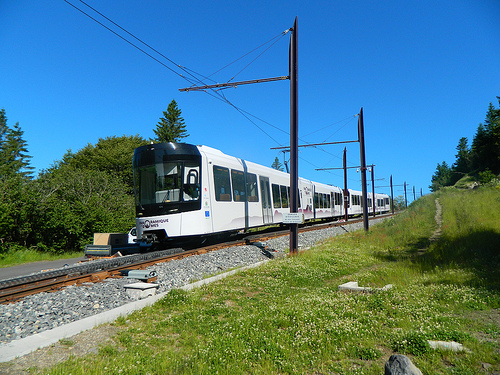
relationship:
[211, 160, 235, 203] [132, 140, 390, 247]
window on a train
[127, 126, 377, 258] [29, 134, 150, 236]
train near trees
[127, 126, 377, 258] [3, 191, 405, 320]
train on tracks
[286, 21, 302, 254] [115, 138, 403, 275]
pole near train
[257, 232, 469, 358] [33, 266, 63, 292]
field next to tracks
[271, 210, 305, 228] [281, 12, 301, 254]
sign on post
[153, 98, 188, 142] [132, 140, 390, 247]
tree behind train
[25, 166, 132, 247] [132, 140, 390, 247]
tree behind train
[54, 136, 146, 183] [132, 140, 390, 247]
tree behind train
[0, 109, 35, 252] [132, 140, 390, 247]
tree behind train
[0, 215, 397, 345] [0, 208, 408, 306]
pebbles along side tracks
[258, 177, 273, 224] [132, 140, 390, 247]
door on train